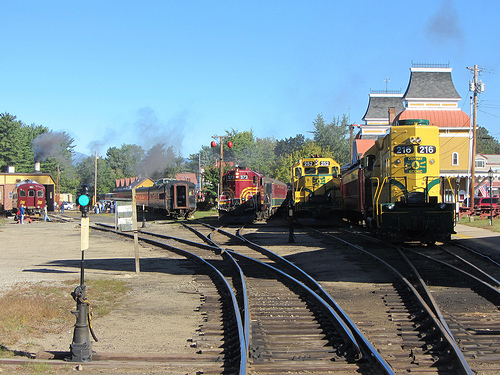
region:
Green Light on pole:
[69, 182, 99, 215]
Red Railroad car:
[7, 177, 58, 229]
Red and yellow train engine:
[214, 165, 281, 226]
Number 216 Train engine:
[355, 119, 473, 253]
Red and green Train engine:
[276, 147, 366, 230]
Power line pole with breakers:
[462, 57, 488, 222]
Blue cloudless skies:
[1, 0, 498, 121]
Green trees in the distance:
[0, 109, 376, 182]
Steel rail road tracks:
[142, 222, 498, 372]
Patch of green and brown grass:
[0, 262, 138, 367]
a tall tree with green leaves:
[0, 104, 78, 176]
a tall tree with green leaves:
[100, 133, 191, 205]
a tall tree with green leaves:
[210, 117, 285, 207]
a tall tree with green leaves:
[295, 110, 347, 187]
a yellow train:
[354, 127, 472, 238]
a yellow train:
[264, 150, 354, 215]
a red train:
[203, 143, 311, 228]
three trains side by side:
[191, 105, 472, 240]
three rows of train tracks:
[166, 240, 496, 354]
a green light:
[55, 176, 130, 264]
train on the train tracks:
[332, 125, 449, 242]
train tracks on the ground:
[203, 251, 363, 373]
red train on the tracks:
[221, 152, 283, 220]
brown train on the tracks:
[142, 172, 203, 225]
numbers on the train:
[395, 142, 436, 162]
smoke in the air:
[128, 118, 182, 197]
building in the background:
[435, 79, 490, 187]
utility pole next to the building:
[467, 60, 484, 233]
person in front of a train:
[15, 200, 29, 222]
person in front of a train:
[37, 197, 54, 239]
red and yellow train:
[218, 150, 353, 220]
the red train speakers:
[205, 141, 235, 207]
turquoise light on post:
[78, 185, 95, 370]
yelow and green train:
[329, 97, 472, 252]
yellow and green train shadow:
[60, 253, 496, 290]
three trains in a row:
[213, 131, 453, 235]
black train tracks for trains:
[194, 232, 404, 373]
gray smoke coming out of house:
[33, 126, 73, 170]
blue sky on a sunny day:
[44, 18, 416, 105]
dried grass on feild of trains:
[30, 248, 140, 345]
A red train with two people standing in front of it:
[11, 182, 56, 226]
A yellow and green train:
[375, 117, 455, 247]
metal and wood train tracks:
[184, 232, 390, 374]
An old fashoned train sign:
[61, 186, 101, 358]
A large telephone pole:
[465, 58, 485, 221]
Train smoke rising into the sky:
[24, 123, 74, 175]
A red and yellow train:
[224, 162, 266, 220]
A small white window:
[449, 149, 462, 167]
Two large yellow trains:
[291, 118, 458, 250]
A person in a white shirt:
[37, 199, 52, 224]